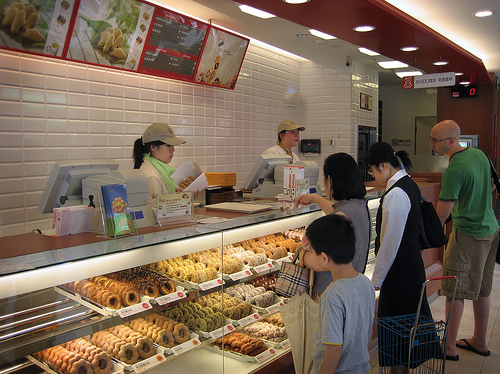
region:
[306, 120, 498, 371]
people standing in front of a doughnut display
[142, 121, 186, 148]
woman wearing a cap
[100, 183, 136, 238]
colorful pamphlet on a counter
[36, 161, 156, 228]
a cash register behind a counter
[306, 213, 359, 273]
a boy with black hair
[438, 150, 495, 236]
man wearing a green shirt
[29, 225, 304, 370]
a selection of doughnuts in a window display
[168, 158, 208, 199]
a woman holding a white box of doughnuts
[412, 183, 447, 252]
woman holding a black purse on her shoulder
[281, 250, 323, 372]
woman holding an umbrella on her wrist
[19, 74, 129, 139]
the wall is tiled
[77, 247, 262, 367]
the pastries in the display case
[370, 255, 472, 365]
the cart behind the woman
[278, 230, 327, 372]
the woman with the umbrella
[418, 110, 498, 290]
the man wearing glasses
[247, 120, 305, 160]
the woman at the cash register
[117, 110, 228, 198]
the woman holding pastries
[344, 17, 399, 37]
the lights on the ceiling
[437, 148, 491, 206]
the man wearing green t shirt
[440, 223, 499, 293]
the man wearing cargo shorts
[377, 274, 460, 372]
small metal cart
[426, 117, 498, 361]
man in green t-shirt leaning forward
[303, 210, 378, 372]
boy in grey shirt looking into display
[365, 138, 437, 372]
woman dressed in black and white looking down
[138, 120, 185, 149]
brown hat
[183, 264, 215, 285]
row of doughnuts in display case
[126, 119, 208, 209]
girl holding white box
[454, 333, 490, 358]
black flip flop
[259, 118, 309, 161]
girl in brown hat helping customer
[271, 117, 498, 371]
group of people standing in front of display case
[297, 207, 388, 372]
A boy wearing a grey shirt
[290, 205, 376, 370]
A boy staring at pastries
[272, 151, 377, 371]
A woman with a white/pink/blue purse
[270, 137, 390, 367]
A woman ordering a pastry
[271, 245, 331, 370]
A closed yellow umbrella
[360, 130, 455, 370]
A woman wearing glasses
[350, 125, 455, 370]
A woman with a black purse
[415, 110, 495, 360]
A man wearing a green shirt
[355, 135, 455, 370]
A woman wearing a black dress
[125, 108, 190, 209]
A woman wearing a tan cap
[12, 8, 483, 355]
customers and staff at doughnut shop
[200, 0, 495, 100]
lights on brown elevated panel on white ceiling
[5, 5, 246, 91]
pictures and menu on elevated red sign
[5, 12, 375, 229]
shiny white tiles covering wall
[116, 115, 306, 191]
women in tan caps working behind counter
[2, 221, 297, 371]
display case with doughnuts in different shapes and colors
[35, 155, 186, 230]
pamphlets and signs in front of cashier screen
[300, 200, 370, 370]
boy looking into display case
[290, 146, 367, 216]
woman with finger pointing from top of cabinet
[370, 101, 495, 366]
man leaning toward woman behind cart